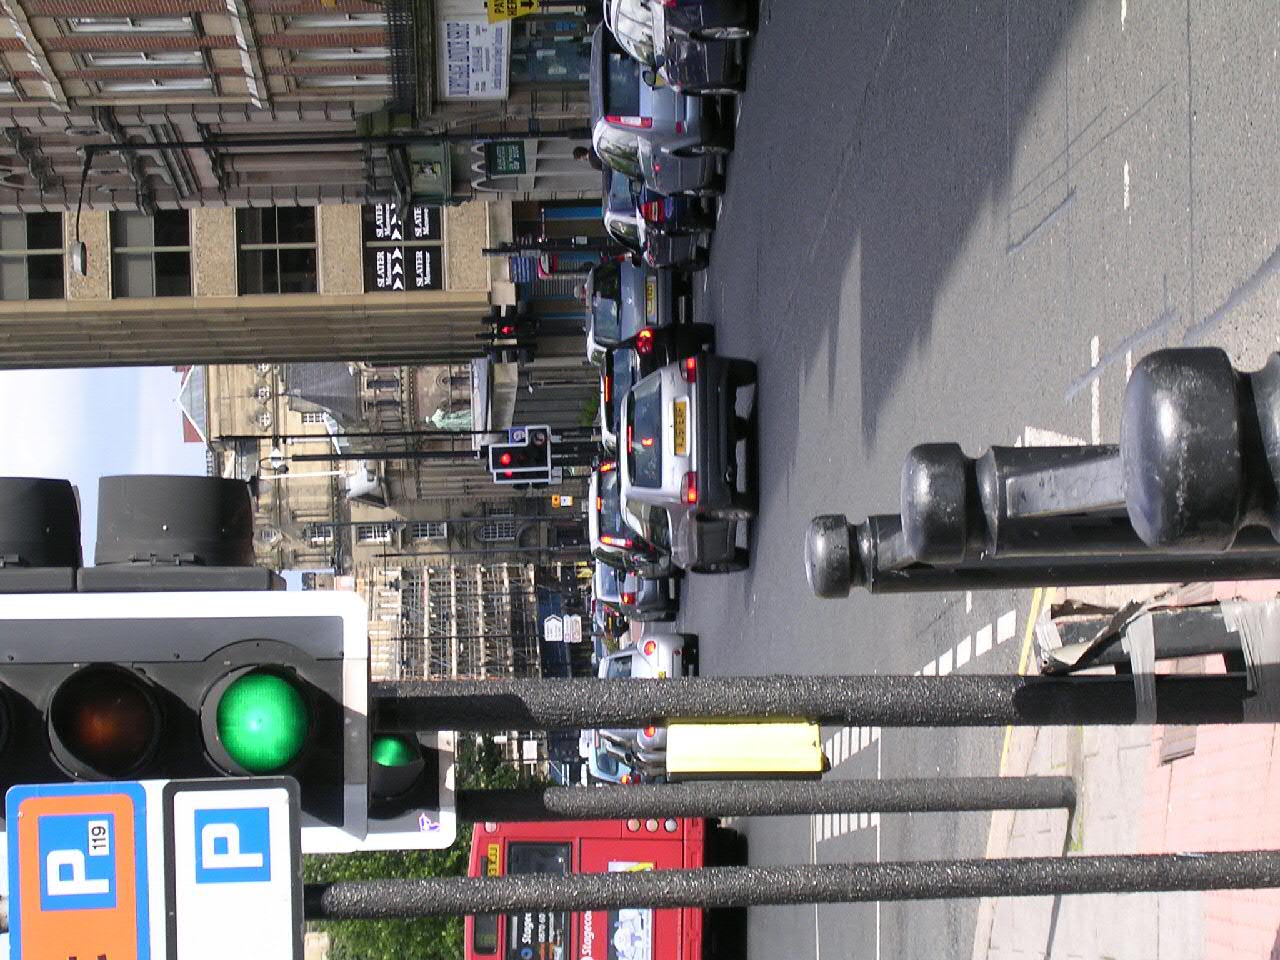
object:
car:
[589, 16, 733, 195]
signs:
[4, 772, 303, 960]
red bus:
[461, 817, 705, 959]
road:
[723, 266, 1016, 400]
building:
[0, 199, 512, 370]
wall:
[0, 298, 496, 370]